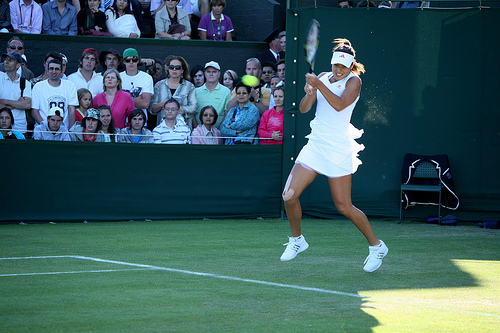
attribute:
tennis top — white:
[305, 70, 367, 142]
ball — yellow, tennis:
[240, 72, 259, 87]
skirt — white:
[295, 123, 364, 175]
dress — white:
[290, 72, 379, 179]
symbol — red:
[329, 81, 344, 94]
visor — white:
[329, 49, 356, 71]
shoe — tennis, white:
[268, 229, 318, 274]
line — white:
[84, 252, 273, 284]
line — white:
[16, 267, 113, 274]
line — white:
[4, 252, 74, 261]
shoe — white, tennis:
[360, 239, 389, 274]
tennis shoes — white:
[263, 231, 405, 276]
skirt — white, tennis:
[294, 137, 361, 180]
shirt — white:
[28, 79, 80, 128]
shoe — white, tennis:
[278, 228, 314, 262]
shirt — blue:
[235, 117, 248, 134]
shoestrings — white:
[284, 238, 301, 249]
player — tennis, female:
[280, 38, 389, 270]